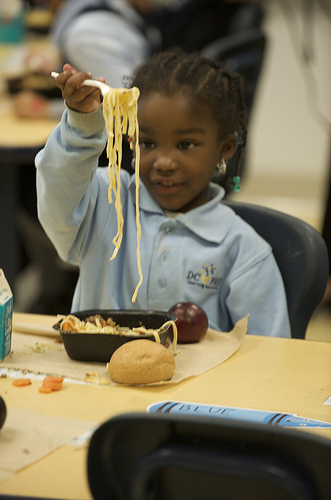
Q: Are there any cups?
A: No, there are no cups.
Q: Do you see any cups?
A: No, there are no cups.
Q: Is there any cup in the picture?
A: No, there are no cups.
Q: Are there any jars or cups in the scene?
A: No, there are no cups or jars.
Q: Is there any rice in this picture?
A: No, there is no rice.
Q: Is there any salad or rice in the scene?
A: No, there are no rice or salad.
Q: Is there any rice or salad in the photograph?
A: No, there are no rice or salad.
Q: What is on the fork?
A: The noodles are on the fork.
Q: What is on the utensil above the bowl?
A: The noodles are on the fork.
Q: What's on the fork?
A: The noodles are on the fork.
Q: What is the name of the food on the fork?
A: The food is noodles.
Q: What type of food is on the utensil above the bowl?
A: The food is noodles.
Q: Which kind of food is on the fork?
A: The food is noodles.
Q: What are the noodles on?
A: The noodles are on the fork.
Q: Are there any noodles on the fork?
A: Yes, there are noodles on the fork.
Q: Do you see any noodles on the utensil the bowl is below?
A: Yes, there are noodles on the fork.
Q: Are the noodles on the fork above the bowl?
A: Yes, the noodles are on the fork.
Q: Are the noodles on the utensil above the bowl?
A: Yes, the noodles are on the fork.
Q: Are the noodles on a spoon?
A: No, the noodles are on the fork.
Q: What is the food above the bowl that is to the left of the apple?
A: The food is noodles.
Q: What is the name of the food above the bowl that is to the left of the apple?
A: The food is noodles.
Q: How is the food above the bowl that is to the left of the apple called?
A: The food is noodles.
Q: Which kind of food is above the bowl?
A: The food is noodles.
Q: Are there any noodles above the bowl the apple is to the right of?
A: Yes, there are noodles above the bowl.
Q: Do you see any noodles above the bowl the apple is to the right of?
A: Yes, there are noodles above the bowl.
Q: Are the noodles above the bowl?
A: Yes, the noodles are above the bowl.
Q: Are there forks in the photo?
A: Yes, there is a fork.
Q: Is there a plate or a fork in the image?
A: Yes, there is a fork.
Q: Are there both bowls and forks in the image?
A: Yes, there are both a fork and a bowl.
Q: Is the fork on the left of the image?
A: Yes, the fork is on the left of the image.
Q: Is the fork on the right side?
A: No, the fork is on the left of the image.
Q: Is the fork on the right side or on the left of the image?
A: The fork is on the left of the image.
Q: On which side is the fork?
A: The fork is on the left of the image.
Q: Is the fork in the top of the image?
A: Yes, the fork is in the top of the image.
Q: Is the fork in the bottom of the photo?
A: No, the fork is in the top of the image.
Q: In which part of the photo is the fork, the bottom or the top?
A: The fork is in the top of the image.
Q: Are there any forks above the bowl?
A: Yes, there is a fork above the bowl.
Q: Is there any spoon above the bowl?
A: No, there is a fork above the bowl.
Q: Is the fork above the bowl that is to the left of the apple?
A: Yes, the fork is above the bowl.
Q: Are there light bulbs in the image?
A: No, there are no light bulbs.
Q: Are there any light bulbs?
A: No, there are no light bulbs.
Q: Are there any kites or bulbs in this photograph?
A: No, there are no bulbs or kites.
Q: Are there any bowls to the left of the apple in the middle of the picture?
A: Yes, there is a bowl to the left of the apple.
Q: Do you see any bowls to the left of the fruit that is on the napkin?
A: Yes, there is a bowl to the left of the apple.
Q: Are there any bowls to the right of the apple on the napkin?
A: No, the bowl is to the left of the apple.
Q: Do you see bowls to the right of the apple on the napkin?
A: No, the bowl is to the left of the apple.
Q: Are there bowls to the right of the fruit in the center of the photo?
A: No, the bowl is to the left of the apple.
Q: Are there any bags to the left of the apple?
A: No, there is a bowl to the left of the apple.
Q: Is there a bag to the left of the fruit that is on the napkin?
A: No, there is a bowl to the left of the apple.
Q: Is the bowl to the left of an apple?
A: Yes, the bowl is to the left of an apple.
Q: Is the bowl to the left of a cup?
A: No, the bowl is to the left of an apple.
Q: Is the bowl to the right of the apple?
A: No, the bowl is to the left of the apple.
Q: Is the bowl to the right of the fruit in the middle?
A: No, the bowl is to the left of the apple.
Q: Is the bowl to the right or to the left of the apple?
A: The bowl is to the left of the apple.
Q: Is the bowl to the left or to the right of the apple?
A: The bowl is to the left of the apple.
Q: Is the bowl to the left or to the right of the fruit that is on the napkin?
A: The bowl is to the left of the apple.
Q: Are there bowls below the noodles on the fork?
A: Yes, there is a bowl below the noodles.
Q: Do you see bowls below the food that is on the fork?
A: Yes, there is a bowl below the noodles.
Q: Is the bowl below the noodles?
A: Yes, the bowl is below the noodles.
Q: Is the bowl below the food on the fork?
A: Yes, the bowl is below the noodles.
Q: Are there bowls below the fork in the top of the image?
A: Yes, there is a bowl below the fork.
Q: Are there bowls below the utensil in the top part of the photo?
A: Yes, there is a bowl below the fork.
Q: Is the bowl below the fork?
A: Yes, the bowl is below the fork.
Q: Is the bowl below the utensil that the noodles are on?
A: Yes, the bowl is below the fork.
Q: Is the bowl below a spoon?
A: No, the bowl is below the fork.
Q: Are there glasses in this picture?
A: No, there are no glasses.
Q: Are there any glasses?
A: No, there are no glasses.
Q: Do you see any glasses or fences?
A: No, there are no glasses or fences.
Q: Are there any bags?
A: No, there are no bags.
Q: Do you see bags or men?
A: No, there are no bags or men.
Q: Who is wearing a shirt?
A: The girl is wearing a shirt.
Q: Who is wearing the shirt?
A: The girl is wearing a shirt.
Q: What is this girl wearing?
A: The girl is wearing a shirt.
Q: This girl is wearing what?
A: The girl is wearing a shirt.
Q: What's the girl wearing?
A: The girl is wearing a shirt.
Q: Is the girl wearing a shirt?
A: Yes, the girl is wearing a shirt.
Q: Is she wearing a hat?
A: No, the girl is wearing a shirt.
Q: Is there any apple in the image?
A: Yes, there is an apple.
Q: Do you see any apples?
A: Yes, there is an apple.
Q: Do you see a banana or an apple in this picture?
A: Yes, there is an apple.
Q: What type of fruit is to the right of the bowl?
A: The fruit is an apple.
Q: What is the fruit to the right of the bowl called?
A: The fruit is an apple.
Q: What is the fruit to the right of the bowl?
A: The fruit is an apple.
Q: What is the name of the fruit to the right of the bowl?
A: The fruit is an apple.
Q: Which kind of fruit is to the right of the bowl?
A: The fruit is an apple.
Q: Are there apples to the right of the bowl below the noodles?
A: Yes, there is an apple to the right of the bowl.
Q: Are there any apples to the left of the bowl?
A: No, the apple is to the right of the bowl.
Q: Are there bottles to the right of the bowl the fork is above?
A: No, there is an apple to the right of the bowl.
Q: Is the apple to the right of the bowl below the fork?
A: Yes, the apple is to the right of the bowl.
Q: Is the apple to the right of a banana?
A: No, the apple is to the right of the bowl.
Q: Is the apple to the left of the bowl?
A: No, the apple is to the right of the bowl.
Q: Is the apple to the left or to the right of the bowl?
A: The apple is to the right of the bowl.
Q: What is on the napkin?
A: The apple is on the napkin.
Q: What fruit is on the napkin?
A: The fruit is an apple.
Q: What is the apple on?
A: The apple is on the napkin.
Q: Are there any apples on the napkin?
A: Yes, there is an apple on the napkin.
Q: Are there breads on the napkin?
A: No, there is an apple on the napkin.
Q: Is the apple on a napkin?
A: Yes, the apple is on a napkin.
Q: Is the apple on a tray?
A: No, the apple is on a napkin.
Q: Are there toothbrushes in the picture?
A: No, there are no toothbrushes.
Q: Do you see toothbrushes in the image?
A: No, there are no toothbrushes.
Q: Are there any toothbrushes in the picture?
A: No, there are no toothbrushes.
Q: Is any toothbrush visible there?
A: No, there are no toothbrushes.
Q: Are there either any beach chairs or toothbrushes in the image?
A: No, there are no toothbrushes or beach chairs.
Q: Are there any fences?
A: No, there are no fences.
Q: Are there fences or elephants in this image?
A: No, there are no fences or elephants.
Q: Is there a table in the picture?
A: Yes, there is a table.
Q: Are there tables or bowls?
A: Yes, there is a table.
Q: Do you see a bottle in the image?
A: No, there are no bottles.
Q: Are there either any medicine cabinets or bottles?
A: No, there are no bottles or medicine cabinets.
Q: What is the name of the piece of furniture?
A: The piece of furniture is a table.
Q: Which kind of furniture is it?
A: The piece of furniture is a table.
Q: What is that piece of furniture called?
A: This is a table.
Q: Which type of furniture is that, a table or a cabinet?
A: This is a table.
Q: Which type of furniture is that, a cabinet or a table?
A: This is a table.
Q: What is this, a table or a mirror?
A: This is a table.